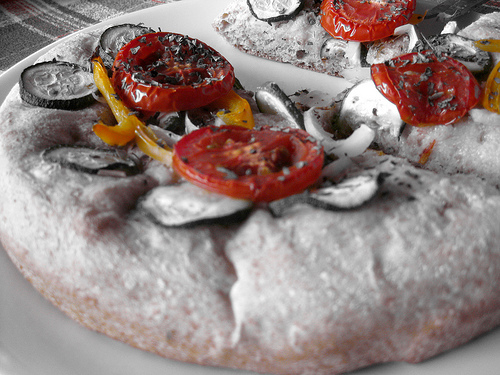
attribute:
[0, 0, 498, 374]
pizza — sliced , small 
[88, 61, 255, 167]
yellow pepper —  yellow 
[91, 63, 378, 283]
bread — Round flat , cut in half.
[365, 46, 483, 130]
tomato — slice 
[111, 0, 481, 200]
tomato — Cut up 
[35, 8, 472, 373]
plate — white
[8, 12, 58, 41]
cloth — checkered 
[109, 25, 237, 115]
tomato — slice, cooked.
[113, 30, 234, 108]
tomato — Cut up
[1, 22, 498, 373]
food — top , on top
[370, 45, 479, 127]
tomato slice — four red tomato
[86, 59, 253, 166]
peppers — Multiple yellow 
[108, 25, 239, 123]
tomato — cooked., red , burnt flesh., Cut up 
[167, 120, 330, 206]
tomato — Cut up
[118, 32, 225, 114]
tomato — slice 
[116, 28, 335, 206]
cut tomato — Cut up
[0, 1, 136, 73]
cloth — white plaid , Grey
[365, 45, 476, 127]
tomato — Cut up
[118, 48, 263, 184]
tomatoes — red 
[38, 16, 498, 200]
veggies — slice 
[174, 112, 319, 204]
tomato — Cut up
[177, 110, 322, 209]
tomato — Cut up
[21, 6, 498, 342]
plate — white 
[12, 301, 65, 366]
plate — white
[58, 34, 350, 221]
food. — top